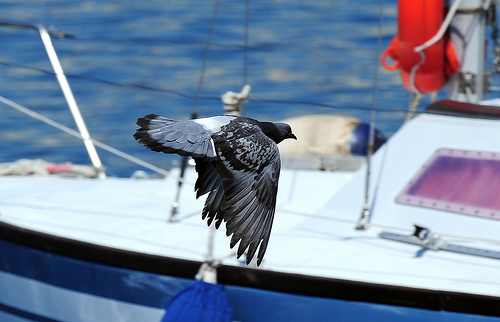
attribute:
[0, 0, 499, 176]
water — blue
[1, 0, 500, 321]
boat — multi colored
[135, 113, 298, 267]
bird — flying, black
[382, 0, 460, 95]
floatation device — orange